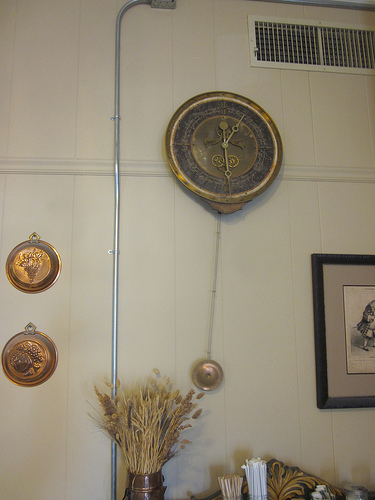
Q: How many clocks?
A: 1.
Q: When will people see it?
A: Soon.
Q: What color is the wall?
A: White.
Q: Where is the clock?
A: On the wall.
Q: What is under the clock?
A: Vase.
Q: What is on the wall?
A: Clock.